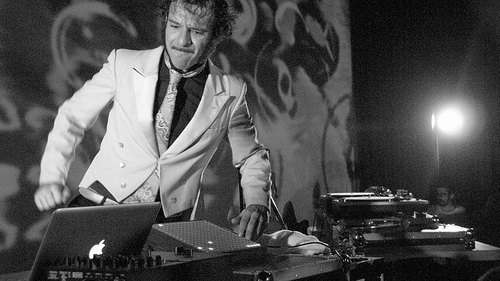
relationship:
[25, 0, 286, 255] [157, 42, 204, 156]
man wearing tie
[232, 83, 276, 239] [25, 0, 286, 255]
arm of a man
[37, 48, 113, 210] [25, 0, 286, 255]
arm of a man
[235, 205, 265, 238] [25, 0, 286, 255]
hand of a man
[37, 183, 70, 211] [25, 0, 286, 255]
hand of a man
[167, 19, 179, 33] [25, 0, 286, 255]
eye of a man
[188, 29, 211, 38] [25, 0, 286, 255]
eye of a man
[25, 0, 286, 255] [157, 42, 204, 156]
man wearing a tie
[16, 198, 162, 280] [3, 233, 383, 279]
laptop on a desk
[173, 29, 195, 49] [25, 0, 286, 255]
nose of a man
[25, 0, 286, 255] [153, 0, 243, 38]
man with hair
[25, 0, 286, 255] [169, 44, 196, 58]
man with moustache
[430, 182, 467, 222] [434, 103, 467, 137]
person under light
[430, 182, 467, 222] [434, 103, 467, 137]
person by light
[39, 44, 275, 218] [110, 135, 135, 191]
jacket has buttons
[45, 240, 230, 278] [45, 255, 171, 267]
equipment with many buttons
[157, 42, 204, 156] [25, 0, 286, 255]
tie on man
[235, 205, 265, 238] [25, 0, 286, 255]
hand on man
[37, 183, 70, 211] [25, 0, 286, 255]
hand on man